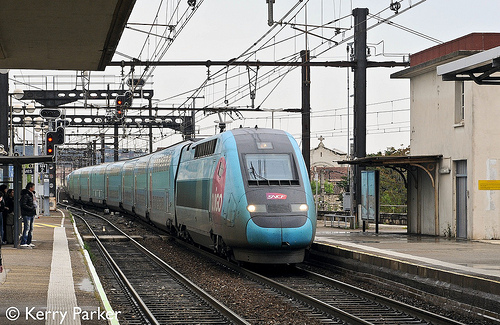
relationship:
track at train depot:
[121, 210, 466, 323] [1, 0, 498, 323]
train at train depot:
[66, 125, 317, 265] [1, 0, 498, 323]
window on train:
[241, 143, 315, 198] [96, 115, 331, 277]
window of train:
[105, 172, 119, 187] [66, 125, 317, 265]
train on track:
[66, 125, 317, 265] [280, 260, 404, 324]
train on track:
[66, 125, 317, 265] [121, 210, 466, 323]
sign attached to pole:
[360, 170, 377, 220] [373, 169, 380, 233]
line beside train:
[39, 200, 88, 320] [44, 135, 373, 276]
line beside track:
[39, 200, 88, 320] [121, 210, 466, 323]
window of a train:
[241, 153, 300, 184] [58, 117, 329, 271]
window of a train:
[147, 170, 172, 195] [76, 119, 319, 262]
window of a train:
[129, 162, 151, 195] [58, 117, 329, 271]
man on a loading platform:
[17, 183, 44, 248] [0, 209, 107, 325]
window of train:
[90, 173, 101, 185] [84, 123, 352, 278]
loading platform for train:
[0, 202, 122, 323] [66, 125, 317, 265]